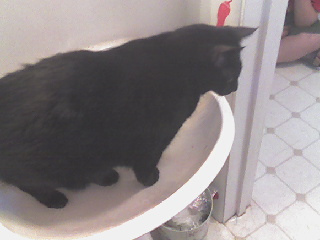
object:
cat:
[0, 23, 262, 209]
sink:
[1, 38, 236, 240]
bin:
[150, 186, 214, 240]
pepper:
[216, 0, 233, 27]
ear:
[232, 25, 259, 39]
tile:
[250, 171, 298, 218]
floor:
[200, 63, 319, 239]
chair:
[277, 0, 319, 64]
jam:
[215, 0, 289, 223]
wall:
[0, 0, 200, 75]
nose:
[232, 84, 238, 94]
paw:
[133, 167, 162, 187]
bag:
[160, 185, 211, 231]